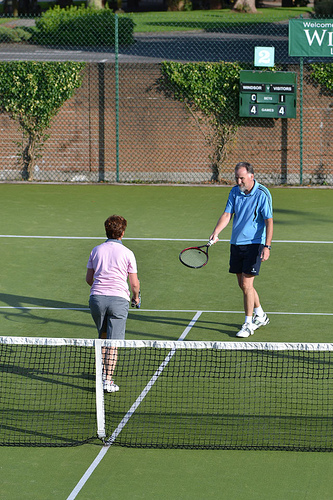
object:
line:
[96, 341, 106, 436]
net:
[0, 345, 96, 447]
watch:
[264, 245, 271, 251]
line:
[0, 235, 35, 237]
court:
[0, 0, 332, 342]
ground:
[277, 182, 311, 188]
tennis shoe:
[236, 324, 254, 337]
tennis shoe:
[254, 313, 270, 330]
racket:
[176, 236, 218, 267]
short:
[229, 244, 264, 275]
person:
[89, 296, 129, 392]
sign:
[254, 46, 274, 66]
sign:
[289, 18, 333, 57]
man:
[210, 163, 273, 338]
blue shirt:
[226, 185, 274, 245]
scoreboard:
[239, 72, 296, 118]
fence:
[0, 0, 331, 187]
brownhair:
[105, 215, 127, 239]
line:
[270, 312, 301, 314]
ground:
[174, 179, 233, 186]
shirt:
[88, 240, 137, 301]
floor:
[275, 185, 332, 240]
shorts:
[88, 296, 129, 340]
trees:
[0, 59, 85, 181]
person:
[209, 163, 273, 337]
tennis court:
[0, 16, 333, 496]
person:
[86, 215, 138, 296]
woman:
[86, 215, 140, 392]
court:
[0, 308, 332, 496]